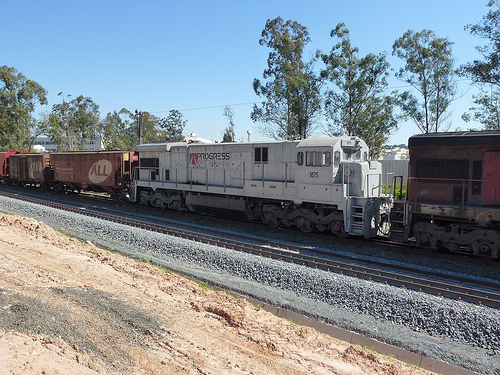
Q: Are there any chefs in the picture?
A: No, there are no chefs.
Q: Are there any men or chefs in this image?
A: No, there are no chefs or men.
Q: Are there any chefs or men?
A: No, there are no chefs or men.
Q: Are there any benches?
A: No, there are no benches.